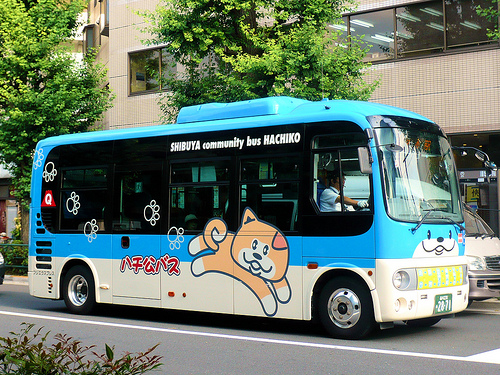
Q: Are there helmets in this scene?
A: No, there are no helmets.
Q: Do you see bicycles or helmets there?
A: No, there are no helmets or bicycles.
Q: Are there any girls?
A: No, there are no girls.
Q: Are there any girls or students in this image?
A: No, there are no girls or students.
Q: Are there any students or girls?
A: No, there are no girls or students.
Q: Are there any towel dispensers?
A: No, there are no towel dispensers.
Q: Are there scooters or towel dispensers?
A: No, there are no towel dispensers or scooters.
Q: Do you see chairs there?
A: No, there are no chairs.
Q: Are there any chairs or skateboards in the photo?
A: No, there are no chairs or skateboards.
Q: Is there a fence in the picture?
A: No, there are no fences.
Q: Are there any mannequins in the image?
A: No, there are no mannequins.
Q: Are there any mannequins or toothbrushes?
A: No, there are no mannequins or toothbrushes.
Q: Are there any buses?
A: Yes, there is a bus.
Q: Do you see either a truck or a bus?
A: Yes, there is a bus.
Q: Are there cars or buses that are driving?
A: Yes, the bus is driving.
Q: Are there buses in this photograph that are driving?
A: Yes, there is a bus that is driving.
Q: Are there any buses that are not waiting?
A: Yes, there is a bus that is driving.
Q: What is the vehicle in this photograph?
A: The vehicle is a bus.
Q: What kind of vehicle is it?
A: The vehicle is a bus.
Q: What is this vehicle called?
A: This is a bus.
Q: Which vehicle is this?
A: This is a bus.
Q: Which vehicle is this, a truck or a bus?
A: This is a bus.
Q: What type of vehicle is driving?
A: The vehicle is a bus.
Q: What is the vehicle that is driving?
A: The vehicle is a bus.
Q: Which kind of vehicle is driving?
A: The vehicle is a bus.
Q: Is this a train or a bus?
A: This is a bus.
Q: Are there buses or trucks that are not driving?
A: No, there is a bus but it is driving.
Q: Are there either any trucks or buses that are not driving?
A: No, there is a bus but it is driving.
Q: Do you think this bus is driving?
A: Yes, the bus is driving.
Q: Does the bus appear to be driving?
A: Yes, the bus is driving.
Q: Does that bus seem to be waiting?
A: No, the bus is driving.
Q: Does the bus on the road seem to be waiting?
A: No, the bus is driving.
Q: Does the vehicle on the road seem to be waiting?
A: No, the bus is driving.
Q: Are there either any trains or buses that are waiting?
A: No, there is a bus but it is driving.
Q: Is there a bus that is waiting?
A: No, there is a bus but it is driving.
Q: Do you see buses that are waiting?
A: No, there is a bus but it is driving.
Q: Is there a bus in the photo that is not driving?
A: No, there is a bus but it is driving.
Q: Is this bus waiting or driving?
A: The bus is driving.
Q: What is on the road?
A: The bus is on the road.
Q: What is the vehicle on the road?
A: The vehicle is a bus.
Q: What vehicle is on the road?
A: The vehicle is a bus.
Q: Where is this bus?
A: The bus is on the road.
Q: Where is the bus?
A: The bus is on the road.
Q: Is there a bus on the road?
A: Yes, there is a bus on the road.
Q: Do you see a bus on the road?
A: Yes, there is a bus on the road.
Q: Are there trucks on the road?
A: No, there is a bus on the road.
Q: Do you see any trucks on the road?
A: No, there is a bus on the road.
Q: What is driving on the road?
A: The bus is driving on the road.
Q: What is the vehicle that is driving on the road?
A: The vehicle is a bus.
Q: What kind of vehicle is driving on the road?
A: The vehicle is a bus.